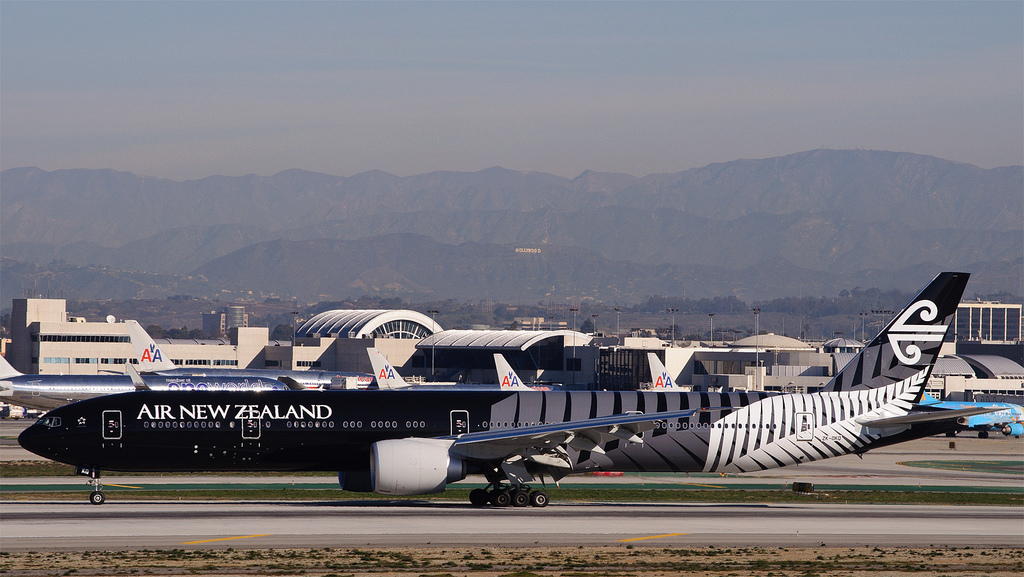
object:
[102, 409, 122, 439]
door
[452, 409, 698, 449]
wing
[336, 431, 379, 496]
turbine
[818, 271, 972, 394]
tail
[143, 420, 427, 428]
windows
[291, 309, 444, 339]
roof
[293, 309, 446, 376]
building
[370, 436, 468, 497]
engine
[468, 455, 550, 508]
landing gear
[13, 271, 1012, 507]
plane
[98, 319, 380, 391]
plane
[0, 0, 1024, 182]
skies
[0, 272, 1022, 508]
airplanes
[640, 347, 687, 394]
plane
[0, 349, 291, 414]
plane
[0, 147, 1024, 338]
mountains